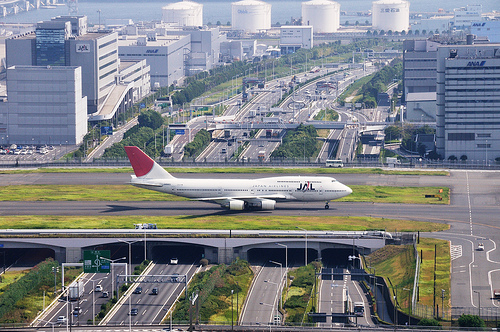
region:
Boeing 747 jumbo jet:
[114, 141, 364, 214]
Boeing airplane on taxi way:
[14, 144, 497, 221]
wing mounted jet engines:
[223, 197, 278, 210]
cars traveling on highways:
[53, 252, 330, 329]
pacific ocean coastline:
[12, 0, 494, 40]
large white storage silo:
[366, 2, 416, 37]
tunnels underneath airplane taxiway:
[8, 231, 376, 270]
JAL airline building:
[11, 15, 149, 136]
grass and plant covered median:
[181, 259, 246, 324]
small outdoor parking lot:
[0, 142, 73, 166]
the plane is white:
[133, 42, 340, 229]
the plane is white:
[75, 82, 487, 315]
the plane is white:
[138, 144, 335, 251]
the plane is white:
[126, 121, 363, 320]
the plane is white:
[179, 116, 353, 225]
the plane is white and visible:
[106, 108, 396, 253]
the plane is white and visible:
[129, 136, 349, 230]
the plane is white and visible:
[137, 146, 354, 326]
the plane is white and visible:
[46, 78, 373, 328]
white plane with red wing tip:
[121, 139, 356, 216]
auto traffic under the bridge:
[5, 240, 391, 329]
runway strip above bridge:
[1, 164, 498, 240]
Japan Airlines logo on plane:
[291, 179, 319, 194]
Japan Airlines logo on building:
[72, 40, 94, 55]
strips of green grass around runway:
[0, 167, 459, 312]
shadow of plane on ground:
[108, 192, 335, 220]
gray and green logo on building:
[461, 57, 493, 69]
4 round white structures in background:
[156, 2, 416, 37]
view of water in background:
[1, 0, 498, 44]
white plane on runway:
[113, 138, 355, 216]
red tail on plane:
[120, 143, 151, 178]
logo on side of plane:
[292, 176, 319, 201]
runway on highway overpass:
[147, 202, 334, 274]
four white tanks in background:
[157, 2, 412, 44]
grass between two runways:
[37, 177, 112, 209]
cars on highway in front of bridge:
[125, 254, 184, 318]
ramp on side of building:
[96, 74, 132, 122]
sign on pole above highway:
[71, 244, 115, 279]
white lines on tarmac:
[460, 200, 490, 282]